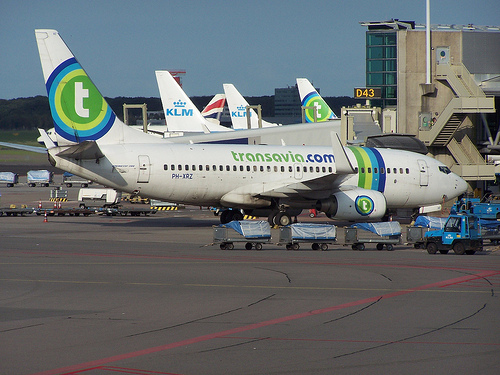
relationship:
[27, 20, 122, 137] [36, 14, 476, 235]
tail of airplane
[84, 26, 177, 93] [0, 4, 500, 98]
clouds in sky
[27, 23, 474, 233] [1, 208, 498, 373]
plane parked tarmac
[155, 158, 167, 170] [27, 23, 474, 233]
window on plane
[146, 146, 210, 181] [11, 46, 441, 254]
window on plane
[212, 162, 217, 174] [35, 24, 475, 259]
window on plane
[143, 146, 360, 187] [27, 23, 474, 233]
window on plane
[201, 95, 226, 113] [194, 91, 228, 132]
stripe on a fin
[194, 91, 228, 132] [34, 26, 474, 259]
fin on an airplane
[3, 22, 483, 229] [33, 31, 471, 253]
airplanes in a line